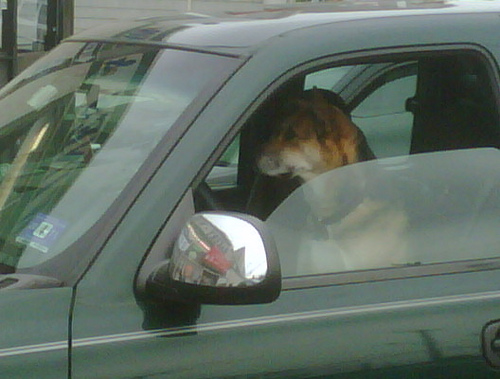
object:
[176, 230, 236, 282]
reflection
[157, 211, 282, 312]
mirror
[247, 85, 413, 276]
dog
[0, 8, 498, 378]
car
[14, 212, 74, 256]
sticker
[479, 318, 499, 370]
handle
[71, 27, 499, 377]
door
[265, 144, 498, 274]
window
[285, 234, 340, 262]
reflection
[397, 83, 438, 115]
seat buckle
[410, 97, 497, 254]
seat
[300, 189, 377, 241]
collar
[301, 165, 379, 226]
neck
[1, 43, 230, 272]
windshield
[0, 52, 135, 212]
reflections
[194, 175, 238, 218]
steering wheel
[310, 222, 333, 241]
tags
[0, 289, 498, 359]
stripe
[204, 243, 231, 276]
awning